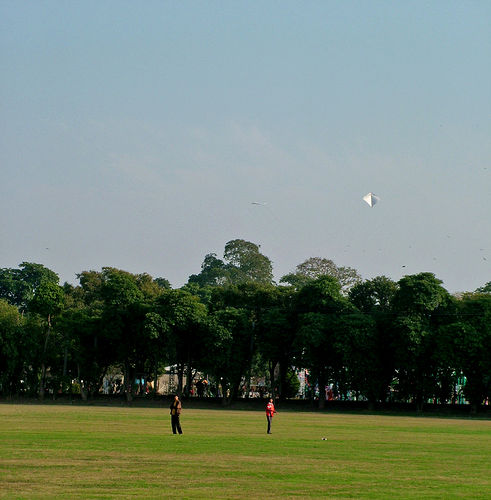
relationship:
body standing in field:
[266, 398, 278, 434] [3, 404, 487, 491]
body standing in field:
[170, 395, 183, 434] [3, 404, 487, 491]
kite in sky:
[362, 193, 380, 208] [0, 3, 488, 294]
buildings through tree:
[157, 351, 470, 405] [436, 283, 491, 414]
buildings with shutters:
[157, 351, 470, 405] [454, 394, 464, 405]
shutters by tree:
[455, 371, 468, 385] [443, 280, 489, 409]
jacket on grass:
[266, 402, 275, 417] [2, 401, 489, 498]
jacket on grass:
[266, 402, 275, 417] [6, 432, 482, 496]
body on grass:
[266, 398, 278, 434] [2, 401, 489, 498]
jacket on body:
[266, 402, 275, 417] [266, 398, 278, 434]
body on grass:
[263, 397, 277, 434] [18, 408, 476, 497]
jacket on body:
[266, 402, 275, 417] [263, 397, 277, 434]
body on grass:
[266, 398, 278, 434] [40, 434, 458, 498]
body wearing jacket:
[266, 398, 278, 434] [246, 401, 299, 441]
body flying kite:
[266, 398, 278, 434] [318, 168, 428, 245]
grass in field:
[2, 401, 489, 498] [0, 403, 490, 499]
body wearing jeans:
[266, 398, 278, 434] [267, 411, 275, 435]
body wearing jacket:
[170, 395, 183, 434] [167, 395, 181, 417]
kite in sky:
[361, 187, 384, 210] [5, 7, 485, 256]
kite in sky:
[362, 193, 380, 208] [154, 156, 216, 202]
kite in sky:
[362, 193, 380, 208] [5, 34, 485, 236]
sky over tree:
[0, 3, 488, 294] [436, 283, 491, 414]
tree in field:
[436, 283, 491, 414] [0, 403, 490, 499]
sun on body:
[149, 383, 295, 445] [266, 398, 278, 434]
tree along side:
[436, 320, 481, 415] [2, 349, 489, 407]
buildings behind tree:
[67, 351, 470, 419] [436, 283, 491, 414]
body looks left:
[170, 395, 183, 434] [11, 24, 39, 472]